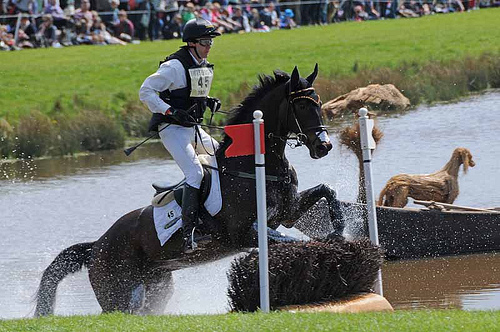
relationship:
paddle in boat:
[411, 195, 488, 211] [339, 193, 499, 255]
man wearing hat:
[137, 16, 222, 256] [182, 18, 219, 40]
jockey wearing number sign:
[138, 17, 220, 250] [196, 69, 217, 91]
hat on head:
[182, 15, 220, 35] [191, 35, 215, 58]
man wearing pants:
[137, 16, 222, 256] [156, 117, 226, 188]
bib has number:
[188, 67, 213, 97] [196, 75, 210, 87]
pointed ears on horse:
[283, 57, 319, 94] [25, 62, 333, 319]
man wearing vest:
[142, 16, 222, 256] [157, 52, 213, 129]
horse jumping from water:
[31, 62, 333, 312] [5, 170, 127, 209]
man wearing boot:
[137, 16, 222, 256] [171, 230, 216, 256]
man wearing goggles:
[142, 16, 222, 256] [191, 36, 211, 44]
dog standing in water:
[376, 146, 474, 207] [0, 88, 498, 318]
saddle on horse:
[144, 160, 217, 211] [25, 62, 333, 319]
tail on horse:
[37, 236, 73, 313] [31, 62, 333, 312]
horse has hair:
[31, 62, 333, 312] [224, 70, 283, 129]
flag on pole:
[220, 106, 312, 325] [250, 108, 270, 317]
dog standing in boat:
[376, 146, 474, 207] [290, 195, 497, 256]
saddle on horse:
[148, 154, 213, 211] [31, 62, 333, 312]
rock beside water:
[315, 82, 412, 117] [0, 88, 498, 318]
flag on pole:
[362, 117, 376, 147] [352, 106, 382, 301]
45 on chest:
[189, 65, 213, 97] [166, 47, 211, 124]